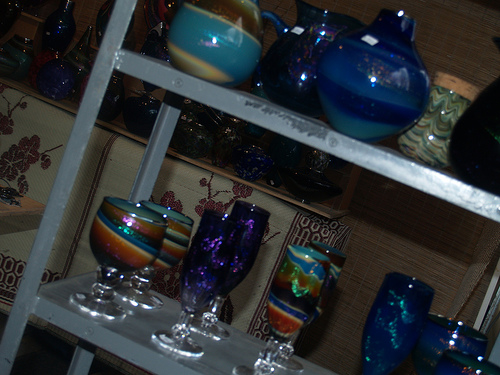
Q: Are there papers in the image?
A: No, there are no papers.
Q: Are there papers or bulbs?
A: No, there are no papers or bulbs.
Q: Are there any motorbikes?
A: No, there are no motorbikes.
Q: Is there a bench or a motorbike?
A: No, there are no motorcycles or benches.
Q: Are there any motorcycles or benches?
A: No, there are no motorcycles or benches.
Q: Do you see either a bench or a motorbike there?
A: No, there are no motorcycles or benches.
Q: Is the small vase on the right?
A: Yes, the vase is on the right of the image.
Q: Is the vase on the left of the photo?
A: No, the vase is on the right of the image.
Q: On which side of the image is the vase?
A: The vase is on the right of the image.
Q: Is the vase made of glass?
A: Yes, the vase is made of glass.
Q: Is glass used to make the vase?
A: Yes, the vase is made of glass.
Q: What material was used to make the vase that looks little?
A: The vase is made of glass.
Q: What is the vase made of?
A: The vase is made of glass.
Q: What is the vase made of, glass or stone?
A: The vase is made of glass.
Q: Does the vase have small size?
A: Yes, the vase is small.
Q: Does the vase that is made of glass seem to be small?
A: Yes, the vase is small.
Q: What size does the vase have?
A: The vase has small size.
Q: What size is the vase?
A: The vase is small.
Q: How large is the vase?
A: The vase is small.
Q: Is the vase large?
A: No, the vase is small.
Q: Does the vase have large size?
A: No, the vase is small.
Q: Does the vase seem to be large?
A: No, the vase is small.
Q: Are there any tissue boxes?
A: No, there are no tissue boxes.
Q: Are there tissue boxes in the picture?
A: No, there are no tissue boxes.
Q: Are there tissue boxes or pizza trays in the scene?
A: No, there are no tissue boxes or pizza trays.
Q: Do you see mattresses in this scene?
A: No, there are no mattresses.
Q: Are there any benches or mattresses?
A: No, there are no mattresses or benches.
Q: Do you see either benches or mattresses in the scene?
A: No, there are no mattresses or benches.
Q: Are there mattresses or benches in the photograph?
A: No, there are no mattresses or benches.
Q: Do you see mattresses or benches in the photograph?
A: No, there are no mattresses or benches.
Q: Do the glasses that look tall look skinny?
A: Yes, the glasses are skinny.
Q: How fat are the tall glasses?
A: The glasses are skinny.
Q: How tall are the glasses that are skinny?
A: The glasses are tall.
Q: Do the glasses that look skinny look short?
A: No, the glasses are tall.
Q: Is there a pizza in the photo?
A: No, there are no pizzas.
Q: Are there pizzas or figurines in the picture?
A: No, there are no pizzas or figurines.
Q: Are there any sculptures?
A: No, there are no sculptures.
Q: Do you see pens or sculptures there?
A: No, there are no sculptures or pens.